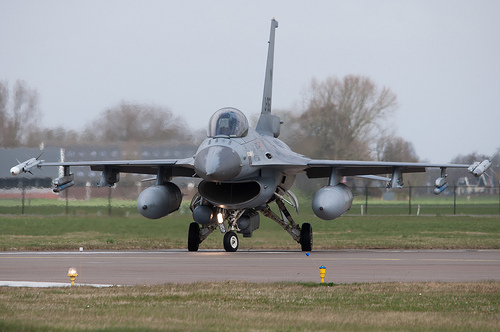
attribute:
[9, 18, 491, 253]
jet — fighter jet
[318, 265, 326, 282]
post — yellow 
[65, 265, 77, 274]
light — blue 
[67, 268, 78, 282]
post — yellow , Small 